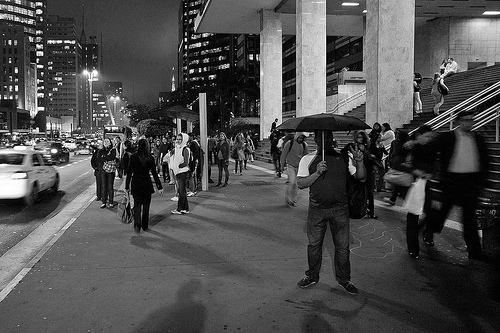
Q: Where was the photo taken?
A: City street.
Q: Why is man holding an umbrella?
A: It is raining.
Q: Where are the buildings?
A: In the distance.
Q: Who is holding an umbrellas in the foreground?
A: A man.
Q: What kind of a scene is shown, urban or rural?
A: Urban.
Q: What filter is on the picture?
A: Black and white.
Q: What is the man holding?
A: An umbrella.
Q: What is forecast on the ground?
A: A shadow.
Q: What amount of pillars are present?
A: Three.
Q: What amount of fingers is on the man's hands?
A: Two.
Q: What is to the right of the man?
A: Couple walking by.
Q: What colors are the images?
A: Black and white.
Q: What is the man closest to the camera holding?
A: An umbrella.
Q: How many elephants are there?
A: None.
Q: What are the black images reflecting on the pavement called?
A: Shadows.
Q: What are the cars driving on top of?
A: The street.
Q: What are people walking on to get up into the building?
A: Stairs.